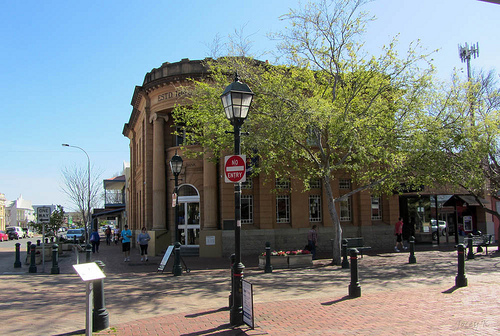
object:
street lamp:
[219, 70, 254, 327]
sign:
[221, 153, 249, 183]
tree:
[169, 0, 499, 265]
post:
[348, 247, 362, 299]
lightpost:
[59, 143, 93, 253]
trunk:
[330, 199, 344, 265]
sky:
[0, 1, 499, 204]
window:
[232, 192, 255, 225]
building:
[120, 54, 498, 260]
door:
[174, 182, 202, 249]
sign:
[35, 205, 53, 225]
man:
[117, 224, 135, 263]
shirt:
[119, 229, 134, 245]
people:
[137, 225, 153, 263]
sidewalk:
[0, 214, 497, 334]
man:
[391, 217, 404, 252]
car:
[0, 230, 9, 242]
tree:
[57, 161, 105, 256]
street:
[0, 233, 51, 272]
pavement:
[0, 267, 499, 335]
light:
[167, 152, 185, 178]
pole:
[171, 174, 181, 278]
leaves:
[167, 1, 499, 206]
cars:
[6, 225, 26, 239]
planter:
[255, 249, 315, 271]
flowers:
[261, 248, 313, 256]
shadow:
[0, 256, 499, 317]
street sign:
[155, 245, 191, 275]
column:
[150, 112, 166, 235]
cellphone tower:
[455, 40, 478, 64]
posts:
[49, 250, 59, 274]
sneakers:
[142, 253, 150, 262]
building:
[5, 194, 35, 230]